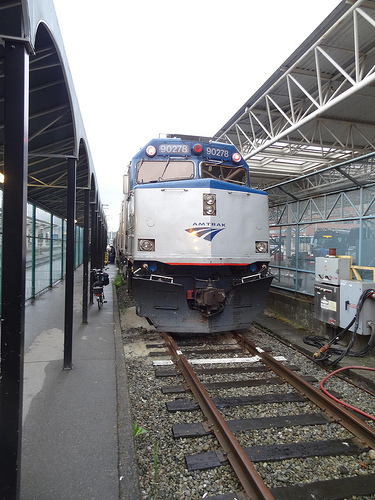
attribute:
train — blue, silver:
[112, 133, 274, 336]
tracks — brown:
[139, 325, 375, 498]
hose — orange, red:
[320, 364, 373, 422]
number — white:
[159, 143, 228, 158]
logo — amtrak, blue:
[183, 221, 228, 243]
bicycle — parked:
[90, 267, 108, 311]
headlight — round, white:
[204, 195, 216, 216]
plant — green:
[132, 419, 148, 437]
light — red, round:
[192, 143, 204, 153]